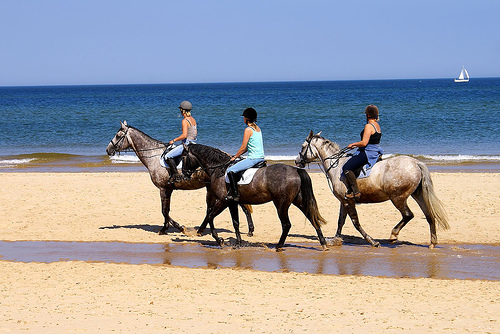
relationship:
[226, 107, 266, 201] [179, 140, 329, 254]
woman on horse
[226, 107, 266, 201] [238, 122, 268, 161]
woman wearing blue top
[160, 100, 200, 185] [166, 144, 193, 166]
woman wearing jeans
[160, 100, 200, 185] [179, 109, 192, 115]
woman has blonde hair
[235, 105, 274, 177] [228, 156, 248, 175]
woman wearing jeans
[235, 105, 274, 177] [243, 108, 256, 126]
woman has hair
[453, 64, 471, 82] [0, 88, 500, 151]
sailboat in ocean water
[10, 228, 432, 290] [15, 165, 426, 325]
wet patch in sand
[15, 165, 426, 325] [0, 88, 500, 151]
sand from ocean water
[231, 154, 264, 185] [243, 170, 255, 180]
saddle with padding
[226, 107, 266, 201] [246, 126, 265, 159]
woman wearing blue top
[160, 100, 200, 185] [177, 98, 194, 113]
woman wearing helmet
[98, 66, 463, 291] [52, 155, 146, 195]
horse walking on beach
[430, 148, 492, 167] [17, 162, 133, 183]
waves washing on shore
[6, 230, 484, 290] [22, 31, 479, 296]
sand on beach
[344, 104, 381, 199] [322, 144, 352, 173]
woman holding reigns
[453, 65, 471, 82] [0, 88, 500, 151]
sailboat on ocean water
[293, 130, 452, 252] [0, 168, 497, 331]
horse on beach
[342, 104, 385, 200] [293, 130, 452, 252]
woman on horse